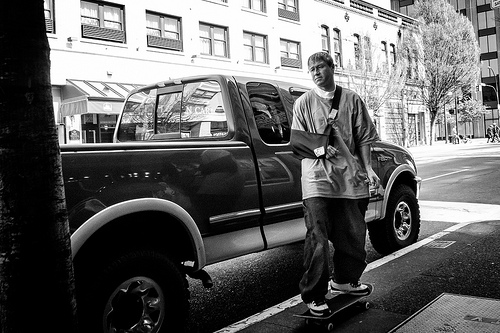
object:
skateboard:
[291, 281, 374, 330]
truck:
[66, 72, 420, 333]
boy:
[286, 51, 380, 311]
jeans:
[299, 195, 367, 305]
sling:
[290, 122, 332, 159]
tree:
[398, 0, 482, 141]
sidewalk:
[409, 140, 495, 159]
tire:
[367, 181, 420, 254]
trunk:
[430, 127, 433, 145]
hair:
[308, 52, 334, 67]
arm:
[291, 136, 325, 158]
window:
[248, 84, 290, 143]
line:
[420, 169, 472, 183]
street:
[424, 150, 495, 254]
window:
[143, 11, 183, 50]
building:
[54, 0, 437, 144]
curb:
[422, 239, 456, 248]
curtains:
[79, 4, 121, 29]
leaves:
[441, 9, 468, 37]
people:
[486, 125, 494, 143]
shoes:
[307, 300, 331, 316]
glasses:
[352, 10, 366, 16]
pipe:
[186, 265, 214, 288]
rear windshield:
[121, 83, 224, 139]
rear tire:
[86, 249, 193, 331]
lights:
[478, 83, 487, 87]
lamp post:
[479, 67, 500, 141]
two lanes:
[424, 156, 499, 183]